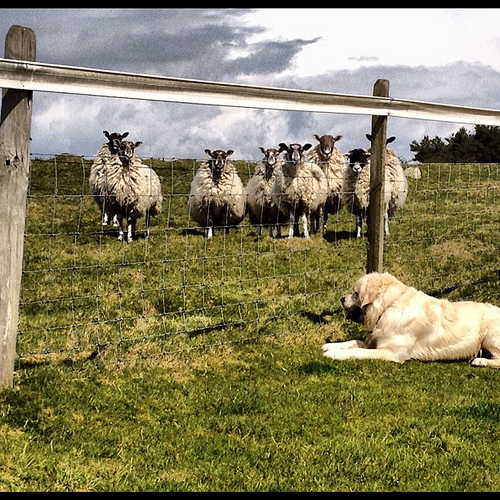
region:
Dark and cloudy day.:
[23, 11, 293, 73]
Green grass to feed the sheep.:
[32, 241, 322, 485]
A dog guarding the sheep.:
[320, 264, 499, 361]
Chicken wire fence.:
[40, 134, 339, 309]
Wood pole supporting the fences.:
[0, 33, 32, 393]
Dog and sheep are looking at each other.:
[91, 125, 498, 372]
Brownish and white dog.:
[306, 270, 497, 362]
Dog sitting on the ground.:
[317, 268, 498, 372]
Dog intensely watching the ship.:
[323, 269, 495, 371]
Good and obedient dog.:
[320, 268, 499, 363]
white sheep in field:
[84, 127, 116, 209]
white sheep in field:
[114, 157, 154, 234]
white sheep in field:
[197, 144, 256, 233]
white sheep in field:
[254, 136, 291, 226]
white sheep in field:
[284, 148, 317, 202]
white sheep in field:
[327, 122, 347, 179]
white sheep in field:
[345, 136, 371, 185]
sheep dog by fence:
[348, 272, 455, 362]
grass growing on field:
[202, 343, 289, 428]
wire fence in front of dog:
[128, 182, 310, 330]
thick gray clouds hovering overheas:
[137, 13, 279, 68]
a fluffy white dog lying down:
[320, 265, 498, 380]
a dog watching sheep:
[314, 272, 498, 385]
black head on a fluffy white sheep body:
[114, 133, 146, 162]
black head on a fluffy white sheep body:
[196, 145, 241, 174]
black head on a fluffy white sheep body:
[256, 141, 282, 173]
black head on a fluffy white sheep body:
[314, 127, 340, 159]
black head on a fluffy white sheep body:
[347, 141, 377, 181]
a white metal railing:
[29, 60, 374, 125]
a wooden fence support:
[6, 80, 27, 382]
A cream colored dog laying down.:
[322, 270, 499, 365]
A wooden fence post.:
[366, 79, 394, 274]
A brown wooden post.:
[1, 18, 33, 386]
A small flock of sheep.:
[88, 130, 373, 242]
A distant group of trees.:
[409, 123, 499, 168]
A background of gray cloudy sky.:
[0, 0, 499, 113]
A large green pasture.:
[1, 152, 498, 499]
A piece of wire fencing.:
[17, 152, 369, 359]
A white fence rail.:
[1, 58, 498, 131]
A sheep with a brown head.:
[302, 132, 347, 237]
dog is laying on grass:
[318, 264, 498, 372]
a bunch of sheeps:
[87, 119, 411, 252]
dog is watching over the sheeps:
[11, 4, 495, 404]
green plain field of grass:
[58, 382, 445, 497]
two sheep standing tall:
[83, 126, 165, 244]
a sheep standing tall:
[190, 146, 254, 238]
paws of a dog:
[319, 331, 403, 366]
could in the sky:
[34, 11, 327, 78]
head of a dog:
[326, 257, 409, 332]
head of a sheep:
[314, 131, 344, 158]